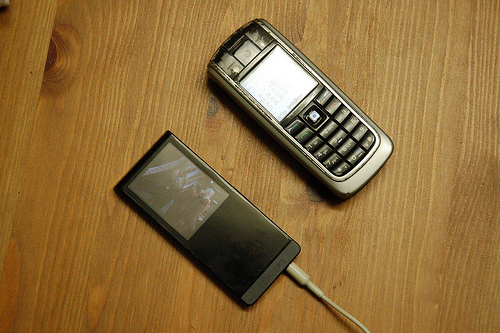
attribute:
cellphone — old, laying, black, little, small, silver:
[204, 17, 403, 203]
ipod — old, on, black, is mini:
[90, 122, 305, 309]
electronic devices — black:
[86, 14, 397, 308]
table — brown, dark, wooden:
[3, 2, 498, 332]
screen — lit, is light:
[126, 136, 232, 240]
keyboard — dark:
[283, 87, 379, 179]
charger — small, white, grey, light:
[285, 259, 371, 333]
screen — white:
[237, 41, 320, 122]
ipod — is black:
[110, 131, 300, 311]